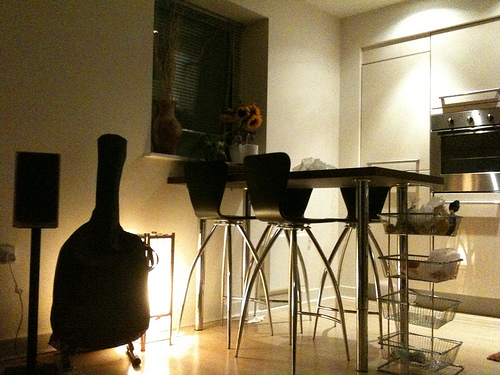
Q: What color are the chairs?
A: Black.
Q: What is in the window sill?
A: Plants.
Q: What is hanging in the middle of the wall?
A: Oven.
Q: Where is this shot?
A: Dining room.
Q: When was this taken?
A: Night time.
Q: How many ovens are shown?
A: 1.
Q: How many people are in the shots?
A: 0.